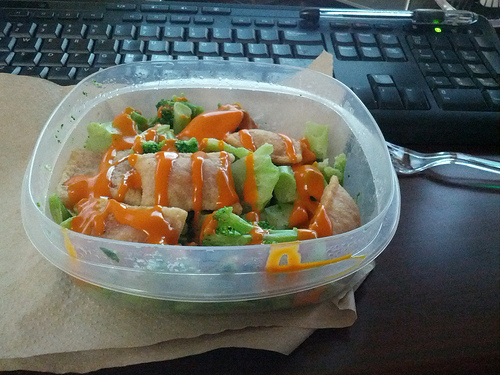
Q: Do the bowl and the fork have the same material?
A: Yes, both the bowl and the fork are made of plastic.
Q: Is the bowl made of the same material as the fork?
A: Yes, both the bowl and the fork are made of plastic.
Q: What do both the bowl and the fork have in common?
A: The material, both the bowl and the fork are plastic.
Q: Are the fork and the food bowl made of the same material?
A: Yes, both the fork and the bowl are made of plastic.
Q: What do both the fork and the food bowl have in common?
A: The material, both the fork and the bowl are plastic.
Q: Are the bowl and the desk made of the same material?
A: No, the bowl is made of plastic and the desk is made of wood.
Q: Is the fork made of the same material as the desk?
A: No, the fork is made of plastic and the desk is made of wood.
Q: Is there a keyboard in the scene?
A: Yes, there is a keyboard.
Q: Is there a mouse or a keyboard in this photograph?
A: Yes, there is a keyboard.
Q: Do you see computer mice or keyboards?
A: Yes, there is a keyboard.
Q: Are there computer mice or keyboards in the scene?
A: Yes, there is a keyboard.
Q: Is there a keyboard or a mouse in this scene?
A: Yes, there is a keyboard.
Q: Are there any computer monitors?
A: No, there are no computer monitors.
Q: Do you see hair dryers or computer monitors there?
A: No, there are no computer monitors or hair dryers.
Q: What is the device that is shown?
A: The device is a keyboard.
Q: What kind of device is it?
A: The device is a keyboard.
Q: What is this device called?
A: This is a keyboard.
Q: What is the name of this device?
A: This is a keyboard.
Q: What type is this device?
A: This is a keyboard.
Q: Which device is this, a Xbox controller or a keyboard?
A: This is a keyboard.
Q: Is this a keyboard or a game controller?
A: This is a keyboard.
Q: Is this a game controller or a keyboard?
A: This is a keyboard.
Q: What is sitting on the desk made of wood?
A: The keyboard is sitting on the desk.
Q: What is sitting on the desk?
A: The keyboard is sitting on the desk.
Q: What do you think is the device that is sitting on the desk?
A: The device is a keyboard.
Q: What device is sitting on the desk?
A: The device is a keyboard.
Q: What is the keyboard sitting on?
A: The keyboard is sitting on the desk.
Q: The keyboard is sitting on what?
A: The keyboard is sitting on the desk.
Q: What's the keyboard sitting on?
A: The keyboard is sitting on the desk.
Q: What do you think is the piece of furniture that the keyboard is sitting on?
A: The piece of furniture is a desk.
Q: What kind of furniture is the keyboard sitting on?
A: The keyboard is sitting on the desk.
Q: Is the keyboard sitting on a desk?
A: Yes, the keyboard is sitting on a desk.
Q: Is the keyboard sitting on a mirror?
A: No, the keyboard is sitting on a desk.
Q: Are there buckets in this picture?
A: No, there are no buckets.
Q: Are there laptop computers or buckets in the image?
A: No, there are no buckets or laptop computers.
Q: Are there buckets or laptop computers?
A: No, there are no buckets or laptop computers.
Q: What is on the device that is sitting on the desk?
A: The pen is on the keyboard.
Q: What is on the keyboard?
A: The pen is on the keyboard.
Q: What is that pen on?
A: The pen is on the keyboard.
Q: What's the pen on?
A: The pen is on the keyboard.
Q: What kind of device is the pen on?
A: The pen is on the keyboard.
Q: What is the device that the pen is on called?
A: The device is a keyboard.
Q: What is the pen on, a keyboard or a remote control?
A: The pen is on a keyboard.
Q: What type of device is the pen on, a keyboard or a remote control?
A: The pen is on a keyboard.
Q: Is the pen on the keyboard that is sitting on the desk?
A: Yes, the pen is on the keyboard.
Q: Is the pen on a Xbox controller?
A: No, the pen is on the keyboard.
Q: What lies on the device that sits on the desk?
A: The pen lies on the keyboard.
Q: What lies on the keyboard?
A: The pen lies on the keyboard.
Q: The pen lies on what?
A: The pen lies on the keyboard.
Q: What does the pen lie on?
A: The pen lies on the keyboard.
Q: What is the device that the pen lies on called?
A: The device is a keyboard.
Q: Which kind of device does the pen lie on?
A: The pen lies on the keyboard.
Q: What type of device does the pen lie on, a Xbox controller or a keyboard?
A: The pen lies on a keyboard.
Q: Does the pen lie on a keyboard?
A: Yes, the pen lies on a keyboard.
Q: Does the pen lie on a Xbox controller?
A: No, the pen lies on a keyboard.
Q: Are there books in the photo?
A: No, there are no books.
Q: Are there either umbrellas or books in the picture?
A: No, there are no books or umbrellas.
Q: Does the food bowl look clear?
A: Yes, the bowl is clear.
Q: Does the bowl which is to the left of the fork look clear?
A: Yes, the bowl is clear.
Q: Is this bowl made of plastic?
A: Yes, the bowl is made of plastic.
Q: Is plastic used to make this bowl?
A: Yes, the bowl is made of plastic.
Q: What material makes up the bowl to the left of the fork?
A: The bowl is made of plastic.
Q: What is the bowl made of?
A: The bowl is made of plastic.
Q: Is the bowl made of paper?
A: No, the bowl is made of plastic.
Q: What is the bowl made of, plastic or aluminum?
A: The bowl is made of plastic.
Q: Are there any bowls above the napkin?
A: Yes, there is a bowl above the napkin.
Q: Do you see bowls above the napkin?
A: Yes, there is a bowl above the napkin.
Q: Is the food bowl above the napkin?
A: Yes, the bowl is above the napkin.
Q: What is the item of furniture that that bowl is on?
A: The piece of furniture is a desk.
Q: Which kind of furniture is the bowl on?
A: The bowl is on the desk.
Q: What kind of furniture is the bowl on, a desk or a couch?
A: The bowl is on a desk.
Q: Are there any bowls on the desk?
A: Yes, there is a bowl on the desk.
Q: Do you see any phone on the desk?
A: No, there is a bowl on the desk.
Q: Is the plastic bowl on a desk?
A: Yes, the bowl is on a desk.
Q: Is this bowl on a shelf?
A: No, the bowl is on a desk.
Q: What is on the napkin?
A: The bowl is on the napkin.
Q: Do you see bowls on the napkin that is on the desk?
A: Yes, there is a bowl on the napkin.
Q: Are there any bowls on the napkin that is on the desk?
A: Yes, there is a bowl on the napkin.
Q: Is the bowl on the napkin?
A: Yes, the bowl is on the napkin.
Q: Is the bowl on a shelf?
A: No, the bowl is on the napkin.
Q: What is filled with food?
A: The bowl is filled with food.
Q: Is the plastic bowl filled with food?
A: Yes, the bowl is filled with food.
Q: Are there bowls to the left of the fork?
A: Yes, there is a bowl to the left of the fork.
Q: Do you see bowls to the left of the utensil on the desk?
A: Yes, there is a bowl to the left of the fork.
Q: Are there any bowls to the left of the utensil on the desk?
A: Yes, there is a bowl to the left of the fork.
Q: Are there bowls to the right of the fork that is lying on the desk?
A: No, the bowl is to the left of the fork.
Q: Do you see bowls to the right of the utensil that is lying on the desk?
A: No, the bowl is to the left of the fork.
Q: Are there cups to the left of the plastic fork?
A: No, there is a bowl to the left of the fork.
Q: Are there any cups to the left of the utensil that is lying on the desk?
A: No, there is a bowl to the left of the fork.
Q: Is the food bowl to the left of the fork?
A: Yes, the bowl is to the left of the fork.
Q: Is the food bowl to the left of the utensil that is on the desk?
A: Yes, the bowl is to the left of the fork.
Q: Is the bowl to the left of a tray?
A: No, the bowl is to the left of the fork.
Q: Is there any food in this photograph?
A: Yes, there is food.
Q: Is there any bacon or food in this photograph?
A: Yes, there is food.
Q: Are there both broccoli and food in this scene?
A: Yes, there are both food and broccoli.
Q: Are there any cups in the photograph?
A: No, there are no cups.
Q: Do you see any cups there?
A: No, there are no cups.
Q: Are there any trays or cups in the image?
A: No, there are no cups or trays.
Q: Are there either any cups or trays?
A: No, there are no cups or trays.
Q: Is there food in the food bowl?
A: Yes, there is food in the bowl.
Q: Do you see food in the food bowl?
A: Yes, there is food in the bowl.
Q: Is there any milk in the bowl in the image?
A: No, there is food in the bowl.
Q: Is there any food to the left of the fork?
A: Yes, there is food to the left of the fork.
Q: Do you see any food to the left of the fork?
A: Yes, there is food to the left of the fork.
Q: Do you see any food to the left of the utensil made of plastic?
A: Yes, there is food to the left of the fork.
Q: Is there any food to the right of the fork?
A: No, the food is to the left of the fork.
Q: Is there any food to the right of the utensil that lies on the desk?
A: No, the food is to the left of the fork.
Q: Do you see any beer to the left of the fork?
A: No, there is food to the left of the fork.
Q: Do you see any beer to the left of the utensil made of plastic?
A: No, there is food to the left of the fork.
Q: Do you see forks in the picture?
A: Yes, there is a fork.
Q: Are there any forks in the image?
A: Yes, there is a fork.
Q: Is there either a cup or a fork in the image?
A: Yes, there is a fork.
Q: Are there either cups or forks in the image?
A: Yes, there is a fork.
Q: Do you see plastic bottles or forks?
A: Yes, there is a plastic fork.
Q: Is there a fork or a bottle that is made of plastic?
A: Yes, the fork is made of plastic.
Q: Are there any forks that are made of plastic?
A: Yes, there is a fork that is made of plastic.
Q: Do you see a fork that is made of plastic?
A: Yes, there is a fork that is made of plastic.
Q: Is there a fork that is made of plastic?
A: Yes, there is a fork that is made of plastic.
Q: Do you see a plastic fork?
A: Yes, there is a fork that is made of plastic.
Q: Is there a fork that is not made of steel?
A: Yes, there is a fork that is made of plastic.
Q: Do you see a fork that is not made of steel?
A: Yes, there is a fork that is made of plastic.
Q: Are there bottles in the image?
A: No, there are no bottles.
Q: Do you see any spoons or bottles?
A: No, there are no bottles or spoons.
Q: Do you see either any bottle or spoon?
A: No, there are no bottles or spoons.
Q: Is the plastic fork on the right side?
A: Yes, the fork is on the right of the image.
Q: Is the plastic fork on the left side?
A: No, the fork is on the right of the image.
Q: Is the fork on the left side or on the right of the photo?
A: The fork is on the right of the image.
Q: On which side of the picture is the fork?
A: The fork is on the right of the image.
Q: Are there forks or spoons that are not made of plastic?
A: No, there is a fork but it is made of plastic.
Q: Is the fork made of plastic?
A: Yes, the fork is made of plastic.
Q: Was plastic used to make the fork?
A: Yes, the fork is made of plastic.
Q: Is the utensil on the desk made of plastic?
A: Yes, the fork is made of plastic.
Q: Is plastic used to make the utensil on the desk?
A: Yes, the fork is made of plastic.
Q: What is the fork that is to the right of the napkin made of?
A: The fork is made of plastic.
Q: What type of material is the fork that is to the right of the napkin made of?
A: The fork is made of plastic.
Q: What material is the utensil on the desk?
A: The fork is made of plastic.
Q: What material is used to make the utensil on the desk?
A: The fork is made of plastic.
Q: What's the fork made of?
A: The fork is made of plastic.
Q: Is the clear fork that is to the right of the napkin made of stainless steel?
A: No, the fork is made of plastic.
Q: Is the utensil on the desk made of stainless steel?
A: No, the fork is made of plastic.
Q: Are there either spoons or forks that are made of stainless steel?
A: No, there is a fork but it is made of plastic.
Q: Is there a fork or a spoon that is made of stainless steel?
A: No, there is a fork but it is made of plastic.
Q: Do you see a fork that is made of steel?
A: No, there is a fork but it is made of plastic.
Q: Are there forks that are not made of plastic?
A: No, there is a fork but it is made of plastic.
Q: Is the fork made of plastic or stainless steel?
A: The fork is made of plastic.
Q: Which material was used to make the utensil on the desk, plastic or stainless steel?
A: The fork is made of plastic.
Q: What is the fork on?
A: The fork is on the desk.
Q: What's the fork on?
A: The fork is on the desk.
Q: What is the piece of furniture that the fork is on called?
A: The piece of furniture is a desk.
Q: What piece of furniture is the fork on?
A: The fork is on the desk.